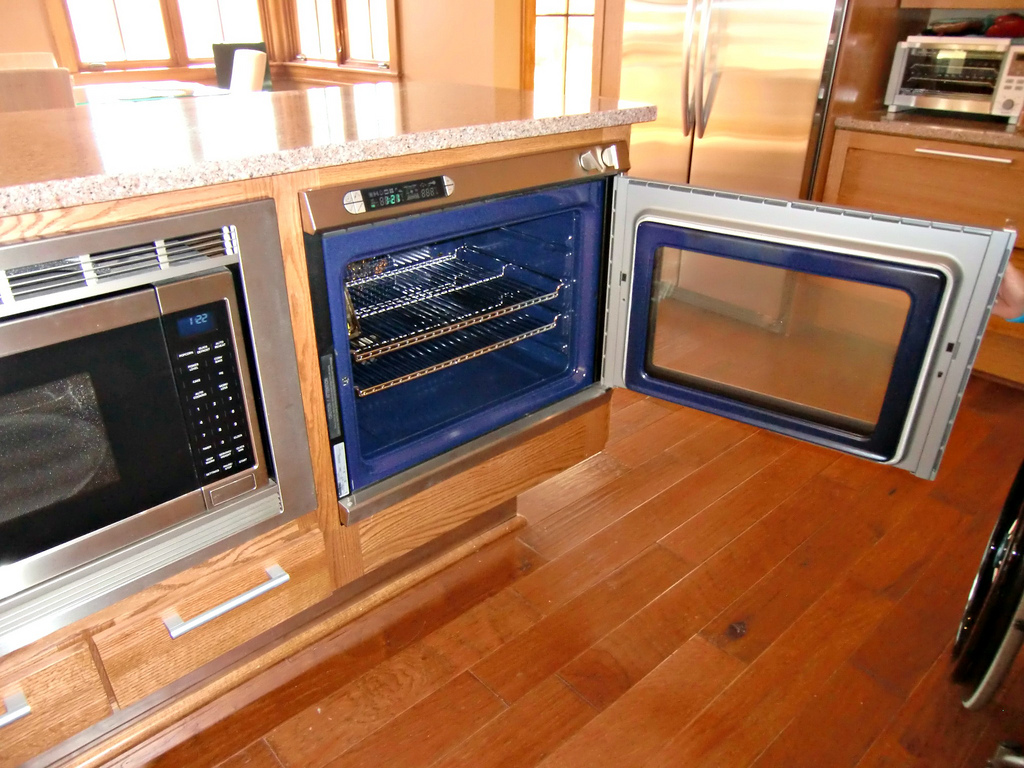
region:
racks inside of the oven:
[346, 277, 569, 417]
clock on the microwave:
[171, 309, 223, 338]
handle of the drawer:
[159, 547, 308, 646]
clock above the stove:
[333, 164, 464, 219]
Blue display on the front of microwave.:
[155, 300, 222, 340]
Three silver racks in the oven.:
[366, 262, 585, 380]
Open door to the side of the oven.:
[593, 164, 966, 475]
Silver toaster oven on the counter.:
[875, 11, 1015, 130]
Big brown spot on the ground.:
[691, 602, 761, 660]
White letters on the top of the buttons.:
[186, 336, 253, 461]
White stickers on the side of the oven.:
[319, 436, 358, 517]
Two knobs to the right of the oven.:
[568, 131, 638, 170]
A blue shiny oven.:
[326, 183, 603, 512]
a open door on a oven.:
[602, 172, 1020, 483]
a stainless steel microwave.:
[2, 195, 315, 655]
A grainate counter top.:
[10, 84, 659, 218]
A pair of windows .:
[289, 1, 391, 71]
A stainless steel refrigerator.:
[615, 1, 840, 166]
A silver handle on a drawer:
[162, 562, 296, 642]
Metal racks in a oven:
[361, 242, 564, 392]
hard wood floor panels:
[161, 297, 1022, 762]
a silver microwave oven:
[2, 196, 322, 662]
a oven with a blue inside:
[296, 179, 1017, 512]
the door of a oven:
[604, 165, 1022, 494]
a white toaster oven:
[875, 26, 1022, 134]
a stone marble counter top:
[6, 75, 655, 213]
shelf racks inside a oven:
[274, 136, 1020, 509]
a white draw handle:
[155, 554, 302, 650]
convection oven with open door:
[294, 132, 1013, 535]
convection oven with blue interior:
[286, 139, 1011, 542]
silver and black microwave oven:
[0, 268, 277, 602]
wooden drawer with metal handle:
[87, 513, 340, 713]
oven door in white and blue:
[599, 165, 1015, 485]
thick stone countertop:
[0, 73, 658, 217]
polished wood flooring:
[147, 288, 1013, 766]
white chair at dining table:
[0, 47, 273, 115]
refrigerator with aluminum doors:
[610, 0, 849, 348]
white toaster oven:
[871, 35, 1021, 127]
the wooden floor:
[654, 625, 760, 708]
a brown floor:
[448, 620, 543, 685]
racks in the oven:
[347, 278, 586, 378]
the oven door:
[651, 193, 927, 438]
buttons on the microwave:
[193, 385, 266, 468]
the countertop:
[278, 95, 361, 138]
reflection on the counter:
[195, 102, 301, 161]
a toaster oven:
[900, 25, 1018, 127]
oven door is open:
[586, 163, 1011, 500]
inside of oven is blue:
[311, 175, 607, 509]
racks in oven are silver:
[333, 238, 577, 410]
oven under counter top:
[291, 131, 1013, 515]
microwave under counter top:
[0, 194, 356, 704]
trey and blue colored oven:
[292, 115, 629, 490]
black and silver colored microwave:
[23, 226, 298, 582]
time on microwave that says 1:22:
[149, 280, 227, 341]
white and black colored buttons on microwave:
[178, 340, 245, 486]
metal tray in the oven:
[337, 229, 568, 324]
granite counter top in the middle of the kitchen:
[8, 49, 637, 196]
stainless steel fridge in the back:
[610, 17, 832, 328]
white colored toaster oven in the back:
[868, 33, 1001, 139]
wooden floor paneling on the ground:
[55, 268, 1019, 766]